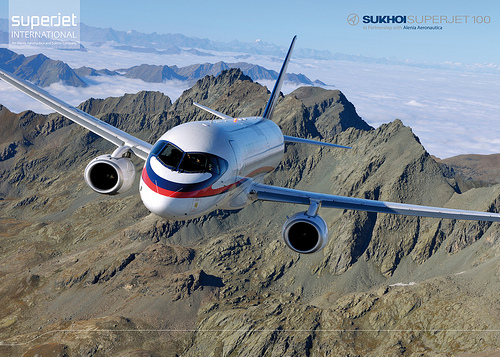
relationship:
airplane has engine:
[1, 34, 500, 255] [283, 208, 327, 257]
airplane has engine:
[1, 34, 500, 255] [80, 153, 134, 196]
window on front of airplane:
[154, 142, 218, 176] [1, 34, 500, 255]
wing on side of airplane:
[249, 180, 499, 223] [1, 34, 500, 255]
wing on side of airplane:
[2, 69, 158, 162] [1, 34, 500, 255]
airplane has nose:
[1, 34, 500, 255] [138, 158, 210, 221]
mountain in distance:
[3, 66, 497, 356] [0, 67, 499, 218]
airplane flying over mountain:
[1, 34, 500, 255] [3, 66, 497, 356]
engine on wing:
[80, 153, 134, 196] [2, 69, 158, 162]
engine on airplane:
[80, 153, 134, 196] [1, 34, 500, 255]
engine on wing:
[283, 208, 327, 257] [249, 180, 499, 223]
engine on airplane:
[283, 208, 327, 257] [1, 34, 500, 255]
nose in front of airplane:
[138, 158, 210, 221] [1, 34, 500, 255]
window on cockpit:
[154, 142, 218, 176] [154, 140, 223, 186]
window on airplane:
[154, 142, 218, 176] [1, 34, 500, 255]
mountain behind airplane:
[3, 66, 497, 356] [1, 34, 500, 255]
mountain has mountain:
[3, 49, 82, 95] [0, 46, 87, 88]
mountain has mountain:
[77, 61, 317, 85] [120, 61, 329, 83]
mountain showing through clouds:
[3, 49, 82, 95] [4, 27, 500, 163]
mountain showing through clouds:
[77, 61, 317, 85] [4, 27, 500, 163]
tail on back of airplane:
[264, 33, 297, 117] [1, 34, 500, 255]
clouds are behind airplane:
[4, 27, 500, 163] [1, 34, 500, 255]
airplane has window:
[1, 34, 500, 255] [154, 142, 218, 176]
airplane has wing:
[1, 34, 500, 255] [249, 180, 499, 223]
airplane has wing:
[1, 34, 500, 255] [2, 69, 158, 162]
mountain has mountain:
[3, 66, 497, 356] [0, 68, 500, 357]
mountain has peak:
[3, 66, 497, 356] [281, 85, 358, 123]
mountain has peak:
[3, 66, 497, 356] [355, 117, 454, 191]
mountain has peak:
[3, 66, 497, 356] [41, 91, 169, 122]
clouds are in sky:
[4, 27, 500, 163] [0, 2, 500, 158]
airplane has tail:
[1, 34, 500, 255] [264, 33, 297, 117]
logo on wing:
[63, 104, 106, 126] [0, 68, 153, 162]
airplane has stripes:
[1, 34, 500, 255] [138, 153, 279, 201]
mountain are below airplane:
[3, 66, 497, 356] [1, 34, 500, 255]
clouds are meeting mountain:
[4, 27, 500, 163] [0, 46, 87, 88]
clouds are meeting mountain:
[4, 27, 500, 163] [120, 61, 329, 83]